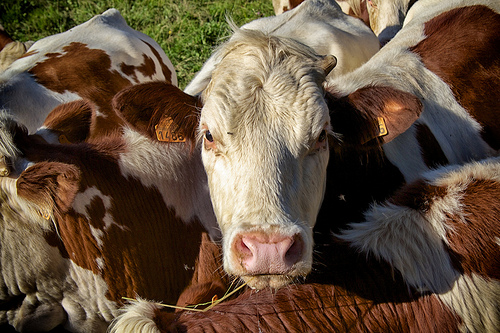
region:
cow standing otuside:
[248, 222, 422, 327]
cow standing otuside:
[34, 20, 122, 88]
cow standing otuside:
[291, 68, 496, 182]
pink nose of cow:
[230, 228, 306, 276]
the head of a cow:
[106, 8, 437, 305]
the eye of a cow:
[196, 120, 218, 157]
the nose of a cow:
[228, 219, 310, 284]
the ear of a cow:
[106, 72, 206, 146]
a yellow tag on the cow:
[150, 113, 192, 148]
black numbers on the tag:
[156, 125, 188, 142]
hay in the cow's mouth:
[118, 270, 262, 315]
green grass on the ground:
[0, 0, 285, 89]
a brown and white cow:
[0, 8, 182, 160]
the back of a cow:
[75, 5, 132, 40]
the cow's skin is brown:
[66, 52, 107, 74]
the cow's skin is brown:
[57, 54, 115, 121]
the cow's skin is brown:
[69, 57, 127, 104]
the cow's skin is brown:
[35, 45, 139, 92]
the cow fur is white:
[153, 2, 361, 257]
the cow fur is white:
[202, 62, 347, 237]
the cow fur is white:
[235, 147, 299, 222]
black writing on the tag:
[157, 128, 187, 142]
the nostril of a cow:
[229, 229, 254, 269]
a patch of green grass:
[1, 0, 283, 94]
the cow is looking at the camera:
[125, 40, 487, 278]